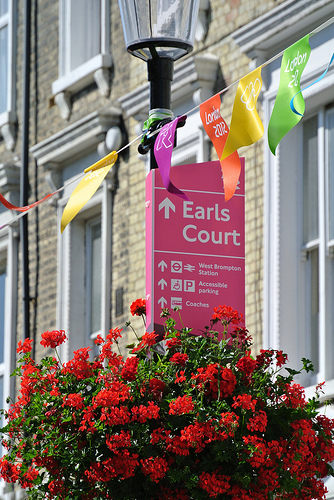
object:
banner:
[153, 115, 190, 204]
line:
[0, 1, 334, 224]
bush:
[0, 295, 334, 498]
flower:
[129, 296, 149, 319]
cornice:
[28, 107, 122, 171]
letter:
[182, 201, 194, 220]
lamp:
[113, 0, 205, 65]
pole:
[147, 55, 175, 170]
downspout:
[17, 0, 29, 344]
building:
[0, 1, 333, 410]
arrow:
[158, 197, 175, 220]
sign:
[145, 156, 245, 348]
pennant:
[267, 30, 312, 156]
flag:
[60, 149, 119, 236]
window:
[271, 72, 334, 411]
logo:
[171, 278, 183, 292]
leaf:
[165, 318, 177, 329]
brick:
[245, 183, 265, 337]